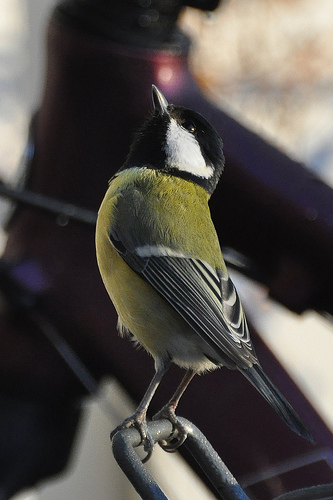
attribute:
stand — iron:
[110, 409, 264, 498]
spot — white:
[163, 117, 213, 179]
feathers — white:
[111, 317, 132, 342]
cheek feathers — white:
[162, 116, 213, 179]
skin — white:
[163, 116, 215, 180]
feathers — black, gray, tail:
[211, 311, 328, 463]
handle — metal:
[111, 415, 248, 499]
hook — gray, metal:
[111, 414, 253, 499]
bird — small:
[95, 84, 315, 498]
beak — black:
[151, 84, 170, 115]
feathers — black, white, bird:
[107, 235, 318, 448]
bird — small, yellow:
[127, 103, 222, 273]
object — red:
[1, 19, 330, 497]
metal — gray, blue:
[110, 419, 243, 496]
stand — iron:
[100, 393, 262, 491]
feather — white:
[169, 126, 200, 169]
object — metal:
[111, 413, 254, 497]